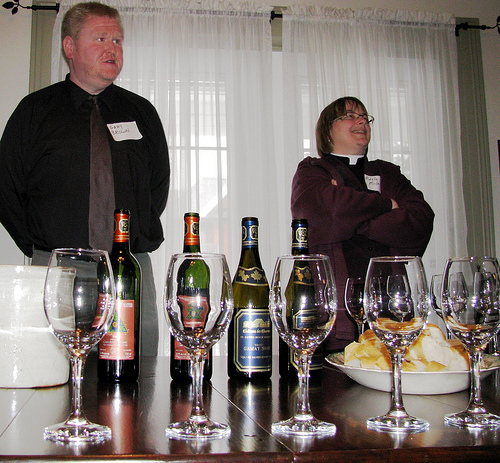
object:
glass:
[38, 238, 108, 453]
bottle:
[231, 212, 276, 381]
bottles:
[95, 210, 141, 383]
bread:
[343, 318, 474, 373]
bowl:
[329, 365, 499, 392]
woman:
[290, 89, 438, 361]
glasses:
[336, 109, 385, 124]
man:
[0, 6, 168, 357]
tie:
[89, 99, 122, 251]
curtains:
[135, 13, 263, 196]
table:
[9, 373, 490, 457]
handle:
[186, 362, 208, 413]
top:
[244, 217, 259, 232]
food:
[350, 325, 478, 373]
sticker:
[237, 309, 284, 372]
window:
[63, 18, 490, 189]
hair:
[57, 8, 81, 31]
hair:
[313, 110, 335, 155]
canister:
[6, 263, 71, 395]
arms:
[353, 169, 435, 250]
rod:
[138, 5, 499, 39]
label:
[100, 297, 138, 357]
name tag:
[105, 117, 144, 148]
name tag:
[358, 176, 391, 198]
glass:
[266, 248, 343, 444]